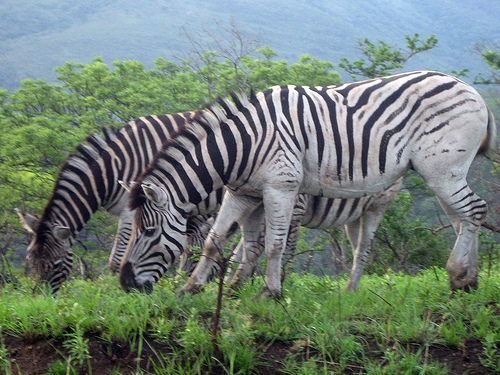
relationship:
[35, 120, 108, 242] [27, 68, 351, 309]
mane on zebra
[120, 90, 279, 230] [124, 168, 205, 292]
mane on forhead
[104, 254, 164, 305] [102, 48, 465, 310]
nose on zebra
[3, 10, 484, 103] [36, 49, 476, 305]
trees are behind zebra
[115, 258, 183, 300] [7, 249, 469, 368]
mouth eating grass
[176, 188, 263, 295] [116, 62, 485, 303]
front leg belonging to zebra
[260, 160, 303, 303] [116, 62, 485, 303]
front leg belonging to zebra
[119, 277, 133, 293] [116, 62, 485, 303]
nose belonging to zebra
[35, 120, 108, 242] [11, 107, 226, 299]
mane belonging to zebra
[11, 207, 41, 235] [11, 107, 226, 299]
ear belonging to zebra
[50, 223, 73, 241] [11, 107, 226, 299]
ear belonging to zebra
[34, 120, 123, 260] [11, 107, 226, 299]
mane belonging to zebra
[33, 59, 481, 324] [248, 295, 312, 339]
zebra in grass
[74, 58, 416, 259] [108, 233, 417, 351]
zebras in field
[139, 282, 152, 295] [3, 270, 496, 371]
mouth grazing in field